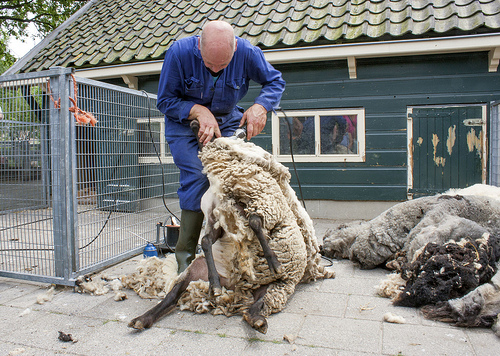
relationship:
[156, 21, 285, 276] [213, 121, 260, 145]
man holding shearer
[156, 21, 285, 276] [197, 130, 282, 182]
man holding head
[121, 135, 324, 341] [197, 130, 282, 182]
sheep has head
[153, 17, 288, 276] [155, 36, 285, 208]
man wearing suit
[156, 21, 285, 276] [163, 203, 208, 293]
man wearing boots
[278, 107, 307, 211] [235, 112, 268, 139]
cord from tool